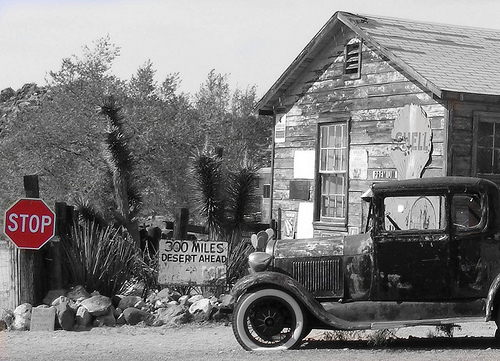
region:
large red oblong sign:
[2, 190, 67, 260]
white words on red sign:
[11, 210, 61, 232]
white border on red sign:
[34, 194, 56, 207]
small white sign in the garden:
[148, 225, 251, 302]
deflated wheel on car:
[232, 278, 302, 358]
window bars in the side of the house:
[302, 110, 354, 180]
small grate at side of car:
[276, 255, 342, 290]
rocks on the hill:
[11, 81, 73, 113]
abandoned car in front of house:
[228, 188, 455, 322]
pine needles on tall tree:
[91, 91, 158, 206]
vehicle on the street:
[224, 158, 499, 350]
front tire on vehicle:
[233, 276, 313, 347]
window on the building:
[317, 118, 346, 220]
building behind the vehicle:
[256, 48, 498, 290]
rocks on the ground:
[68, 295, 209, 314]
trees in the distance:
[8, 70, 255, 209]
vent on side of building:
[336, 49, 370, 79]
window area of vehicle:
[386, 198, 443, 228]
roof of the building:
[355, 13, 496, 95]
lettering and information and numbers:
[163, 243, 225, 264]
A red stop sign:
[0, 195, 73, 333]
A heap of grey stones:
[20, 294, 125, 319]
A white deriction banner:
[145, 236, 239, 291]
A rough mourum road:
[63, 331, 129, 359]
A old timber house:
[240, 34, 482, 241]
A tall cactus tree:
[80, 99, 152, 229]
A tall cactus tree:
[188, 139, 232, 239]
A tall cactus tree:
[224, 148, 271, 236]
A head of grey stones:
[143, 272, 235, 335]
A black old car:
[225, 189, 499, 284]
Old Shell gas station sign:
[386, 103, 433, 178]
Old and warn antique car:
[229, 174, 499, 352]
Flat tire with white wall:
[231, 281, 308, 353]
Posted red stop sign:
[1, 194, 58, 249]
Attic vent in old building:
[338, 40, 362, 80]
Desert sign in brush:
[156, 237, 233, 282]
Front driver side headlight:
[247, 249, 275, 271]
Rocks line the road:
[0, 282, 234, 330]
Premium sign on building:
[371, 168, 398, 181]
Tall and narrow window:
[308, 115, 353, 230]